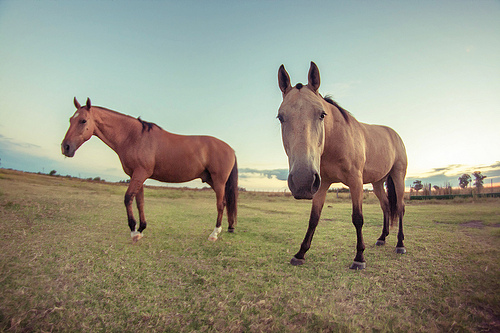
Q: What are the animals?
A: Horses.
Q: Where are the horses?
A: In the field.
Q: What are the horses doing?
A: Standing.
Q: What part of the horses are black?
A: Tails and manes.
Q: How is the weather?
A: Clear.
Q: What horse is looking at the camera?
A: The ligher horse.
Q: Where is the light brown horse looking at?
A: The camera.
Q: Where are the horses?
A: At the field.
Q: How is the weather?
A: Sunny.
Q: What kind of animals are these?
A: Horses.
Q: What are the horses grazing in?
A: Grass.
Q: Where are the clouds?
A: In the sky.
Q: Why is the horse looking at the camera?
A: He's curious.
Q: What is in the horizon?
A: Trees and sky.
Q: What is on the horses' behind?
A: Their tails.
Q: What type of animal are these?
A: Horses.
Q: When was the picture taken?
A: Before Sunset.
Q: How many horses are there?
A: Two.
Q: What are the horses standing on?
A: The grass.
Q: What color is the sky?
A: Blue.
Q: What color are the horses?
A: Brown.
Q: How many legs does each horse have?
A: Four.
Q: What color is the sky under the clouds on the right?
A: Orange.